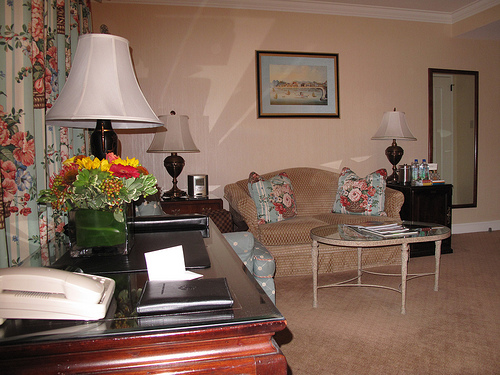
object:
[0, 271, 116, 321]
base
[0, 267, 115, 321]
receiver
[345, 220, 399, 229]
magazines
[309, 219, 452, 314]
coffee table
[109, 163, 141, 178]
flower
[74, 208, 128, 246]
vase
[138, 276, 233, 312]
paper book